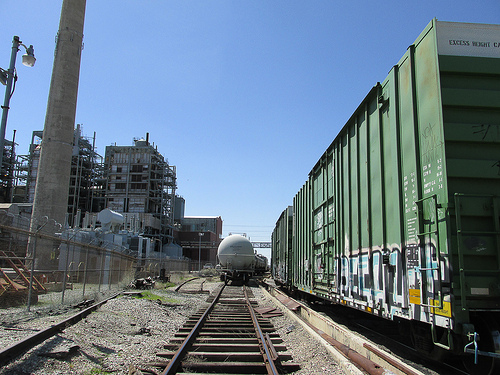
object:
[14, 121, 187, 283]
building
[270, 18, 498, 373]
cars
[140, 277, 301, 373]
railroad tracks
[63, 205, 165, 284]
equipment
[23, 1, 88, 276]
pillar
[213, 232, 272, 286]
cart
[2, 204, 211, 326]
fence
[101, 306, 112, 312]
gravel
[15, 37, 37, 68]
street light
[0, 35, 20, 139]
pole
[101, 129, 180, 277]
building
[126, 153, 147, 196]
stories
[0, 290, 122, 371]
pipes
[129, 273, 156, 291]
building supplies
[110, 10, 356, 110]
sky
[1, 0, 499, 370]
scene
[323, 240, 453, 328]
art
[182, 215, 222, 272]
buildings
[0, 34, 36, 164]
lamp post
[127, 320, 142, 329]
patch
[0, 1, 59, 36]
sky